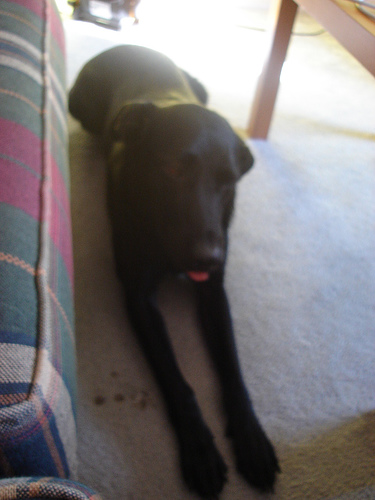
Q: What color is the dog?
A: Black.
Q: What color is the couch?
A: Red, green, blue, white, and yellow.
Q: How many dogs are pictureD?
A: One.